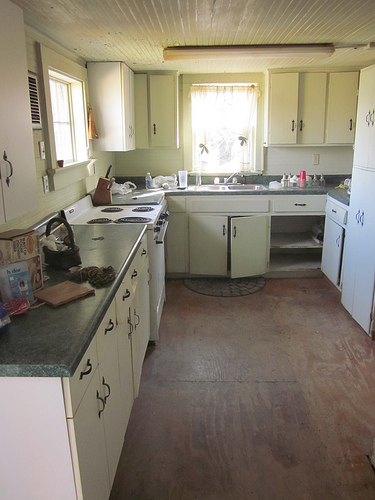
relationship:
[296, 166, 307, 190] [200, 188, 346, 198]
can sitting on top of counter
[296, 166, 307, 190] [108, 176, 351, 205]
can sitting on top of counter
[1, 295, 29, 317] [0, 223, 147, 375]
can sitting on top of counter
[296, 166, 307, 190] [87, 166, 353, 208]
can sitting on top of counter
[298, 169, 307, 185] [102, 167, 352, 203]
can sitting on top of counter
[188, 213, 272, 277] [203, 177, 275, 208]
cabinet underneath sink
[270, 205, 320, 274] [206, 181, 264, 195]
cabinet underneath sink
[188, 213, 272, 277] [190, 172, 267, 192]
cabinet underneath sink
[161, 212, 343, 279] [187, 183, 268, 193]
cabinet under sink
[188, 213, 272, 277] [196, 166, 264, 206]
cabinet under sink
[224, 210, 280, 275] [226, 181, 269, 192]
open cabinet under sink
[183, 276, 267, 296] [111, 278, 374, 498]
mat on floor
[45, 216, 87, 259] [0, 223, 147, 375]
brown basket on counter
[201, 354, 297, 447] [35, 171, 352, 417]
wood floor in kitchen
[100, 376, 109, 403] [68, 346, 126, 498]
handle on cabinet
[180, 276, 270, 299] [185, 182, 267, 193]
mat in front of sink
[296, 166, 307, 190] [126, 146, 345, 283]
can on counter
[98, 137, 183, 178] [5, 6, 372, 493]
wall in kitchen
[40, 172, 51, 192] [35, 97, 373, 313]
electrical outlet on wall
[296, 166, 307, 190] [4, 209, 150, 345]
can on counter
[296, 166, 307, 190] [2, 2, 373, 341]
can in kitchen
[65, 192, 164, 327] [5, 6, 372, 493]
stove in kitchen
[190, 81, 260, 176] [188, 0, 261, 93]
curtains over window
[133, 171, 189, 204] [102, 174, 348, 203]
bottle on counter top